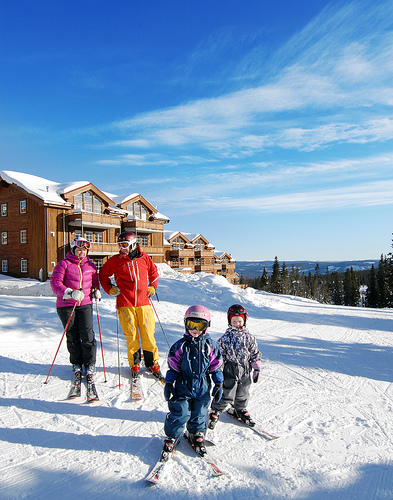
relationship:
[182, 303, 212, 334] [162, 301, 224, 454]
head of child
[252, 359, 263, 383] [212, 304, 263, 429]
hand of boy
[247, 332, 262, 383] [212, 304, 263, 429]
arm of boy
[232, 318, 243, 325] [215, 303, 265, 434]
eyes of boy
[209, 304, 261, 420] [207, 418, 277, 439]
boy wearing skis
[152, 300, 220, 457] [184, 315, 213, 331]
child wearing goggles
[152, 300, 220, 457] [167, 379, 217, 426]
child wearing pants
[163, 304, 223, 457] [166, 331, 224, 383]
person wearing jacket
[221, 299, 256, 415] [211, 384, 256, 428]
person wearing boots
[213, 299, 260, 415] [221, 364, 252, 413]
person wearing pants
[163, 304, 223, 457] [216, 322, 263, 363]
person wearing gray jacket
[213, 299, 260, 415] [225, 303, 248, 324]
person wearing helmet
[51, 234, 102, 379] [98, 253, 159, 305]
person with jacket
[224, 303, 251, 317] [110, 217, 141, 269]
goggles with helmet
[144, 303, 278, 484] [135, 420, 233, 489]
two children with skis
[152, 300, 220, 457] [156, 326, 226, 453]
child with snowsuit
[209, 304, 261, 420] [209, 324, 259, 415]
boy with snowsuit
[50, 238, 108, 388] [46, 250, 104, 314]
woman with coat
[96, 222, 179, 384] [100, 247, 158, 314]
skiier with coat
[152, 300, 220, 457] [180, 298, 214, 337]
child with helmet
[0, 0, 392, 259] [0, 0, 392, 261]
sky with clouds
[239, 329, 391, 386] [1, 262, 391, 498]
shadow on snow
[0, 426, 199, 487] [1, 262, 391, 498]
reflection on snow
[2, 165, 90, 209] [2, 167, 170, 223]
snow on roof